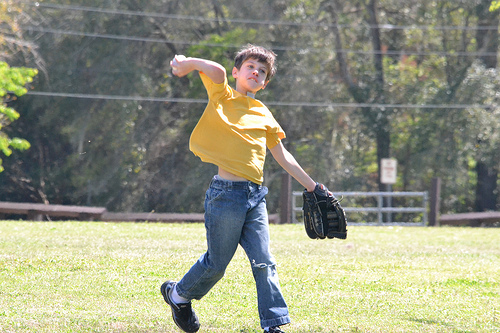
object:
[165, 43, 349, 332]
boy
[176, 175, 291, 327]
blue jeans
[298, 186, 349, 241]
baseball mitt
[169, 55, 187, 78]
baseball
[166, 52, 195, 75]
hand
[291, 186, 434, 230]
gate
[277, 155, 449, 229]
wood posts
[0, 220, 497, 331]
field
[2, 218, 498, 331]
grass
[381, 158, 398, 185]
sign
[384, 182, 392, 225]
pole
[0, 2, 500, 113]
lines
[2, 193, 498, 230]
fence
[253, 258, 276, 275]
tear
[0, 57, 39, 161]
leaves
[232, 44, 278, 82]
hair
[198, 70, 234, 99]
sleeve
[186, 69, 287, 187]
short sleeves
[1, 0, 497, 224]
trees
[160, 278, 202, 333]
sneakers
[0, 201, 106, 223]
bench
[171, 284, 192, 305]
socks